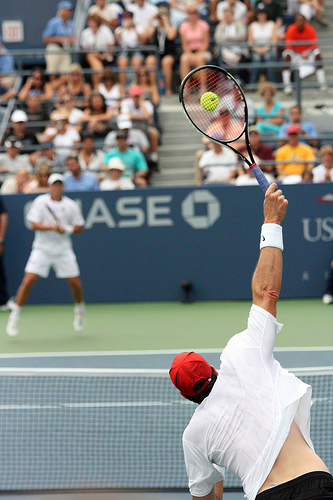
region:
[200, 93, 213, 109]
a tennis ball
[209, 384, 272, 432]
a white shirt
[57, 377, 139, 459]
a tennis net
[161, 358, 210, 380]
man is wearing a red hat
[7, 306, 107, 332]
person is wearing white shoes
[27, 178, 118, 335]
man is jumping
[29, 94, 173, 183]
people in the crowd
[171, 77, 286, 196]
man holding a tennis racket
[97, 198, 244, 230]
a chase logo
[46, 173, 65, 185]
man wearing a white hat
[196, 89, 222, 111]
A tennis ball.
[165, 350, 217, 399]
A red baseball cap.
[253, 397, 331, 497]
The tennis player's visible back.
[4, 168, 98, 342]
The opponent of the tennis player in the foreground.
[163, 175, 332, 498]
The tennis player in the foreground.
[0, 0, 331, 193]
The crowd watching tennis.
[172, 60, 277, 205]
The tennis raquet.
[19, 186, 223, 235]
Advertisement for Chase.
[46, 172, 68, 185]
A white baseball cap.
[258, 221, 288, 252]
A white Nike armband.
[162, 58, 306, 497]
the man swinging the tennis racket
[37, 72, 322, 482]
two men playing tennis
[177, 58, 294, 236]
the tennis racket hitting the tennis ball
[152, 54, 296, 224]
the tennis racket is black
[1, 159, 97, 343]
the man is jumping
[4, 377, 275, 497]
the net on the tennis court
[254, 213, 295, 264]
the wristband on the wrist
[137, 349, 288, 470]
the man wearing the red cap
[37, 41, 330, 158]
spectators in the stands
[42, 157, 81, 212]
the man wearing a white cap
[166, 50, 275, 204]
a black tennis racket with a ball behind it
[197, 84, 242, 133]
a yellow tennis ball behind the racket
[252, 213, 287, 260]
a white wrist band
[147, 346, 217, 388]
a red cap on the player's head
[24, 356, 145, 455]
a white tennis net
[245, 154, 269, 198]
the gray handle on a tennis racket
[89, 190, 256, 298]
a blue wall in a tennis court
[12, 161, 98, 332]
a man in white waiting for the ball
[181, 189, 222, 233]
the white Chase bank logo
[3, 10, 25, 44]
a blurry red and white exit sign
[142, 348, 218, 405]
red baseball hat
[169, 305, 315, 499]
short sleeve white tennis shirt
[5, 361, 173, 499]
tennis net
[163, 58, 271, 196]
black and gray tennis racket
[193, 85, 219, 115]
tennis ball on a racket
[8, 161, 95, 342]
tennis player wearing white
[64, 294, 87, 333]
white tennis shoe and sock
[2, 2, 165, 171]
crowd of spectators watching tennis match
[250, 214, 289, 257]
white sports wrist band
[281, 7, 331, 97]
man wearing a red shirt